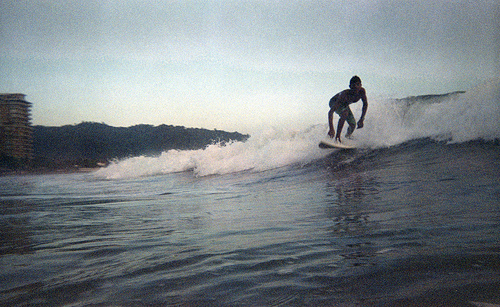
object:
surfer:
[327, 74, 368, 144]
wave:
[91, 75, 496, 180]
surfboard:
[318, 139, 357, 149]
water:
[4, 172, 487, 302]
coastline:
[1, 151, 102, 174]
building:
[1, 92, 36, 171]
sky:
[2, 2, 498, 94]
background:
[2, 2, 498, 216]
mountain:
[33, 120, 250, 168]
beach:
[2, 165, 96, 177]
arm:
[359, 93, 368, 121]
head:
[349, 75, 363, 93]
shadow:
[321, 155, 381, 271]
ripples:
[68, 234, 405, 303]